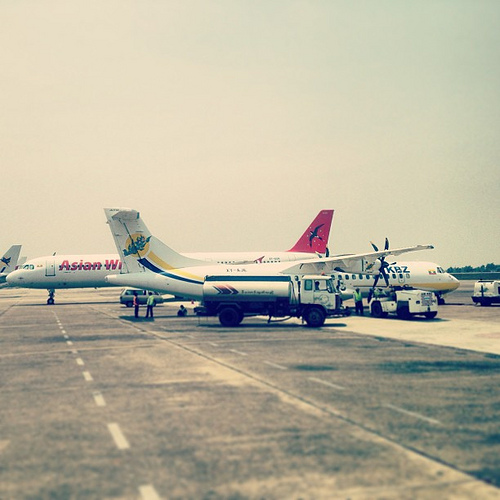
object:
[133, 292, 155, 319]
people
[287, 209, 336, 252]
tail fin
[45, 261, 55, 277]
door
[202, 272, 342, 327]
truck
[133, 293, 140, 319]
person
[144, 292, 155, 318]
person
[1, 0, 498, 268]
skies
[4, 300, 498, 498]
road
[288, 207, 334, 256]
stabilizer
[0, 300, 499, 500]
runway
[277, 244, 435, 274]
wing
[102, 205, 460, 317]
airplane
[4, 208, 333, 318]
airplane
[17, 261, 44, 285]
cockpit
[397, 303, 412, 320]
wheel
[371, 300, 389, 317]
wheel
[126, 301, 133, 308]
wheel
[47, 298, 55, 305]
wheel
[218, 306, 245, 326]
wheel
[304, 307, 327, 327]
wheel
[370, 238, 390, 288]
propeller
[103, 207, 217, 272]
tail fin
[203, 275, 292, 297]
logo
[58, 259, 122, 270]
writing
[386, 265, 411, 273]
writing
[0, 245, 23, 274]
plane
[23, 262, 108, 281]
side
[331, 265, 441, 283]
side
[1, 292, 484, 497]
landing strip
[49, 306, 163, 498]
lines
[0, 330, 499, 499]
street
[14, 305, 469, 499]
tarmac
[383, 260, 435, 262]
edge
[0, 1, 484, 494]
day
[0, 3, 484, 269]
cloud